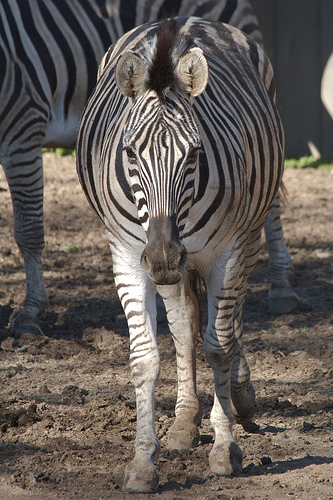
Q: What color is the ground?
A: Grey.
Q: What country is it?
A: South Africa.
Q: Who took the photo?
A: Max.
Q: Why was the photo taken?
A: For an album.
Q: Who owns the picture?
A: Zeke.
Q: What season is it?
A: Summer.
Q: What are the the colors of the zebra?
A: Black and white.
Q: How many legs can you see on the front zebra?
A: Four.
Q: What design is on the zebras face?
A: Stripes.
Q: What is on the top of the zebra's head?
A: Hair.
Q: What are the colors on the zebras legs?
A: White and black.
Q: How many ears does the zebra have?
A: Two.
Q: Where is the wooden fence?
A: In the back.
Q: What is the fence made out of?
A: Wide boards.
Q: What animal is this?
A: Zebra.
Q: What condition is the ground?
A: Muddy.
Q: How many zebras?
A: Two.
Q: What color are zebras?
A: Black and white.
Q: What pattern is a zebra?
A: Striped.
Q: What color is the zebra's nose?
A: Black.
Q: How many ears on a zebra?
A: Two.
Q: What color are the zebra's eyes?
A: Black.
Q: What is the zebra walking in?
A: Dirt.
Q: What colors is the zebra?
A: Black and white.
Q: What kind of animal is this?
A: Zebra.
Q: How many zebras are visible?
A: Two.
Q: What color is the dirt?
A: Brown.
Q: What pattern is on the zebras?
A: Stripes.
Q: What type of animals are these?
A: Zebras.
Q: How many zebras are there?
A: Two.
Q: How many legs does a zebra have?
A: Four.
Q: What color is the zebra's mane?
A: Black.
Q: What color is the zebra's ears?
A: White.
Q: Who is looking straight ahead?
A: The zebra.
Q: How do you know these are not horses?
A: Zebras have stripes.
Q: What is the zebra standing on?
A: Dirt.